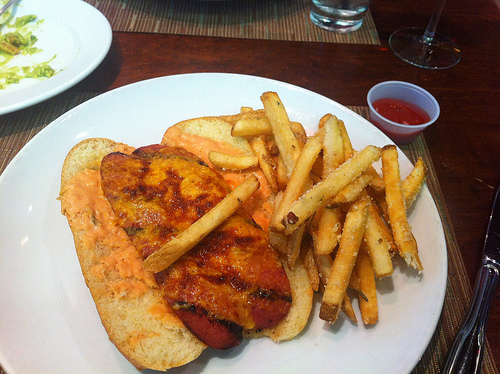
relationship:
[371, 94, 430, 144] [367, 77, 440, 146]
ketchup inside cup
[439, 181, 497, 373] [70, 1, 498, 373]
knife on top of table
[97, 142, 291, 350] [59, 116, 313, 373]
meat on top of bun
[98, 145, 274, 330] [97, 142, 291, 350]
cheese on top of meat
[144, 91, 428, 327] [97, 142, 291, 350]
fries next to meat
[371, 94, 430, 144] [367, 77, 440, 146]
ketchup inside of cup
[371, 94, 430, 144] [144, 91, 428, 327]
ketchup for fries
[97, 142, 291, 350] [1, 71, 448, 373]
meat on top of plate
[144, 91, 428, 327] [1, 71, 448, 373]
fries on top of plate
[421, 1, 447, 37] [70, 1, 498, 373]
glass stem on top of table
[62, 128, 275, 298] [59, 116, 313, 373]
sauce covered on bun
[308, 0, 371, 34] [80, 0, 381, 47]
glass on top of placemat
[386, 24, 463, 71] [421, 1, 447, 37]
bottom of glass stem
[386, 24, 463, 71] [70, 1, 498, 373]
bottom on top of table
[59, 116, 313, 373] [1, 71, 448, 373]
bun on top of plate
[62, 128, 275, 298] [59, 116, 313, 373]
sauce on top of bun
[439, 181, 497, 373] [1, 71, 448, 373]
knife beside plate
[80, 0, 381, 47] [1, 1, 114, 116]
placemat behind plate